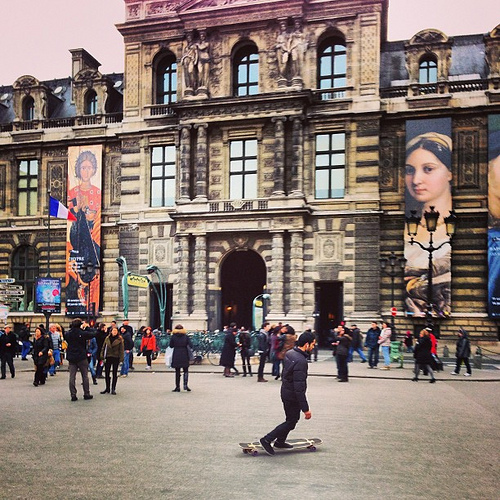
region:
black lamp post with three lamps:
[349, 204, 458, 356]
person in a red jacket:
[130, 322, 159, 370]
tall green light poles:
[94, 241, 178, 332]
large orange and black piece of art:
[40, 206, 107, 325]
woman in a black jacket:
[165, 322, 188, 409]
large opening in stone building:
[101, 211, 348, 320]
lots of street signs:
[0, 265, 31, 312]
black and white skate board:
[220, 435, 347, 491]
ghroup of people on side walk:
[334, 297, 462, 449]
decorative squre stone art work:
[300, 224, 352, 283]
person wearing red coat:
[136, 316, 158, 366]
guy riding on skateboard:
[248, 321, 375, 488]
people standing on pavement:
[57, 313, 175, 428]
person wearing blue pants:
[373, 309, 403, 378]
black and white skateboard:
[233, 436, 341, 466]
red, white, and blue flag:
[33, 181, 95, 241]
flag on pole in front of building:
[29, 187, 140, 306]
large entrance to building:
[177, 204, 336, 354]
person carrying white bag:
[155, 317, 208, 409]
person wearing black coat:
[210, 321, 250, 393]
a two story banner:
[62, 144, 108, 319]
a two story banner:
[396, 117, 458, 323]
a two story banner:
[488, 112, 498, 319]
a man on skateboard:
[237, 329, 339, 460]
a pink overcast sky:
[3, 0, 123, 83]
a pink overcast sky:
[382, 0, 495, 40]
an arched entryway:
[204, 242, 269, 331]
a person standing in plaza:
[62, 311, 94, 403]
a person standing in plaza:
[163, 321, 196, 395]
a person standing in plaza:
[328, 327, 353, 381]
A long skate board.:
[237, 424, 324, 457]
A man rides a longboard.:
[237, 321, 322, 471]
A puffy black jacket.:
[277, 348, 314, 420]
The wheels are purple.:
[240, 443, 259, 455]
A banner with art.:
[406, 119, 451, 319]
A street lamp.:
[403, 202, 458, 358]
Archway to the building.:
[206, 241, 273, 339]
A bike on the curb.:
[190, 336, 222, 369]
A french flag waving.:
[41, 187, 80, 222]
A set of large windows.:
[141, 24, 356, 214]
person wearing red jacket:
[138, 325, 161, 369]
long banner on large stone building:
[400, 118, 454, 317]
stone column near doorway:
[270, 229, 285, 320]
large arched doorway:
[217, 245, 269, 331]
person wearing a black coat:
[166, 323, 195, 391]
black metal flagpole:
[46, 191, 49, 312]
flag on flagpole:
[48, 196, 78, 223]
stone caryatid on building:
[273, 17, 295, 86]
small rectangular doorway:
[314, 280, 344, 350]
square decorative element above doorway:
[313, 230, 343, 261]